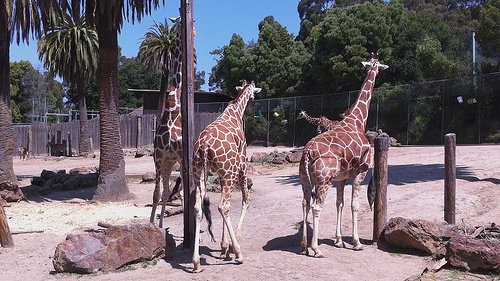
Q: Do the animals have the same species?
A: Yes, all the animals are giraffes.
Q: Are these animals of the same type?
A: Yes, all the animals are giraffes.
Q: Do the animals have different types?
A: No, all the animals are giraffes.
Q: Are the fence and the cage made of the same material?
A: Yes, both the fence and the cage are made of metal.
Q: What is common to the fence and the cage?
A: The material, both the fence and the cage are metallic.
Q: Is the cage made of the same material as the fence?
A: Yes, both the cage and the fence are made of metal.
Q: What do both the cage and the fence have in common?
A: The material, both the cage and the fence are metallic.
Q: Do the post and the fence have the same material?
A: No, the post is made of wood and the fence is made of metal.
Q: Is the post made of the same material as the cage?
A: No, the post is made of wood and the cage is made of metal.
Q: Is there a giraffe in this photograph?
A: Yes, there is a giraffe.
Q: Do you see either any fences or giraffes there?
A: Yes, there is a giraffe.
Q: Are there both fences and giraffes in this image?
A: Yes, there are both a giraffe and a fence.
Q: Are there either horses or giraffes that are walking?
A: Yes, the giraffe is walking.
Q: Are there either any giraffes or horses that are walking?
A: Yes, the giraffe is walking.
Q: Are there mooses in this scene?
A: No, there are no mooses.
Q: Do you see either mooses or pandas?
A: No, there are no mooses or pandas.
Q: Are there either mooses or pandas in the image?
A: No, there are no mooses or pandas.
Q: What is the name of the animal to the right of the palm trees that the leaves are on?
A: The animal is a giraffe.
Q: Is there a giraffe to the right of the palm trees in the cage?
A: Yes, there is a giraffe to the right of the palm trees.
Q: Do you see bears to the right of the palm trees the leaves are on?
A: No, there is a giraffe to the right of the palm trees.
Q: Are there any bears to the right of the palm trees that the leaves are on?
A: No, there is a giraffe to the right of the palm trees.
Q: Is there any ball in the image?
A: No, there are no balls.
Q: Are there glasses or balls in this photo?
A: No, there are no balls or glasses.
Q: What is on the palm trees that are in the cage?
A: The leaves are on the palm trees.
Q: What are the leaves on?
A: The leaves are on the palm trees.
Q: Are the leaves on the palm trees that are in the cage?
A: Yes, the leaves are on the palm trees.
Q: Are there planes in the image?
A: No, there are no planes.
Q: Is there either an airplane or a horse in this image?
A: No, there are no airplanes or horses.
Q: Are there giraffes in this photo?
A: Yes, there is a giraffe.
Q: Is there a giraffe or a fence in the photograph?
A: Yes, there is a giraffe.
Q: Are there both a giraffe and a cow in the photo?
A: No, there is a giraffe but no cows.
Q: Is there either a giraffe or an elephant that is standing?
A: Yes, the giraffe is standing.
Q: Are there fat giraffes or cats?
A: Yes, there is a fat giraffe.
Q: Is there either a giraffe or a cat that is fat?
A: Yes, the giraffe is fat.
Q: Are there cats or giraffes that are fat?
A: Yes, the giraffe is fat.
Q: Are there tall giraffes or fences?
A: Yes, there is a tall giraffe.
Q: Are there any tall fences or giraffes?
A: Yes, there is a tall giraffe.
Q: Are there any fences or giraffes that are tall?
A: Yes, the giraffe is tall.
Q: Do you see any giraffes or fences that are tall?
A: Yes, the giraffe is tall.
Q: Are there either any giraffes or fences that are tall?
A: Yes, the giraffe is tall.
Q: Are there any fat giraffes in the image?
A: Yes, there is a fat giraffe.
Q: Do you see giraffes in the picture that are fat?
A: Yes, there is a giraffe that is fat.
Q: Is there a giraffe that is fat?
A: Yes, there is a giraffe that is fat.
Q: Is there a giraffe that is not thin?
A: Yes, there is a fat giraffe.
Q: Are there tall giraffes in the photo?
A: Yes, there is a tall giraffe.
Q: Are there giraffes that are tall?
A: Yes, there is a giraffe that is tall.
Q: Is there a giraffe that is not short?
A: Yes, there is a tall giraffe.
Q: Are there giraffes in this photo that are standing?
A: Yes, there is a giraffe that is standing.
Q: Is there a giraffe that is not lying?
A: Yes, there is a giraffe that is standing.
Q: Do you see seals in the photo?
A: No, there are no seals.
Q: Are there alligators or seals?
A: No, there are no seals or alligators.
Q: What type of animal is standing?
A: The animal is a giraffe.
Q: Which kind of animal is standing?
A: The animal is a giraffe.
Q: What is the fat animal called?
A: The animal is a giraffe.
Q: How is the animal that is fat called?
A: The animal is a giraffe.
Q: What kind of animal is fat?
A: The animal is a giraffe.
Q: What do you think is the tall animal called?
A: The animal is a giraffe.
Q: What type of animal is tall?
A: The animal is a giraffe.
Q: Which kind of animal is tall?
A: The animal is a giraffe.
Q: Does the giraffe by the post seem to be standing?
A: Yes, the giraffe is standing.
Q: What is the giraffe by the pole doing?
A: The giraffe is standing.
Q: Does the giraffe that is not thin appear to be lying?
A: No, the giraffe is standing.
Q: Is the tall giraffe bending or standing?
A: The giraffe is standing.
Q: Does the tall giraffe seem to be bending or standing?
A: The giraffe is standing.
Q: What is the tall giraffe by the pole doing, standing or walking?
A: The giraffe is standing.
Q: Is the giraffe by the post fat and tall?
A: Yes, the giraffe is fat and tall.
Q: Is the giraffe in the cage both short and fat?
A: No, the giraffe is fat but tall.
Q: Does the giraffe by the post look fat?
A: Yes, the giraffe is fat.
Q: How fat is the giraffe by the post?
A: The giraffe is fat.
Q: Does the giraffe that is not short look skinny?
A: No, the giraffe is fat.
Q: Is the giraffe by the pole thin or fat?
A: The giraffe is fat.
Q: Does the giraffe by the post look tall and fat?
A: Yes, the giraffe is tall and fat.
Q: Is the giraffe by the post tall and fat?
A: Yes, the giraffe is tall and fat.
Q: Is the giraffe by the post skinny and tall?
A: No, the giraffe is tall but fat.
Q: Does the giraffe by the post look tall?
A: Yes, the giraffe is tall.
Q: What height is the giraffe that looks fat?
A: The giraffe is tall.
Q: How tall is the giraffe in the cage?
A: The giraffe is tall.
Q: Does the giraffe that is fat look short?
A: No, the giraffe is tall.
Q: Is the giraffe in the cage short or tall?
A: The giraffe is tall.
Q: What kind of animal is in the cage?
A: The animal is a giraffe.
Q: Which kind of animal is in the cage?
A: The animal is a giraffe.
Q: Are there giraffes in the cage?
A: Yes, there is a giraffe in the cage.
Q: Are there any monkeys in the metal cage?
A: No, there is a giraffe in the cage.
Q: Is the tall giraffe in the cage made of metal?
A: Yes, the giraffe is in the cage.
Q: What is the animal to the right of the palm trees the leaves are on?
A: The animal is a giraffe.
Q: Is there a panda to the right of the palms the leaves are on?
A: No, there is a giraffe to the right of the palms.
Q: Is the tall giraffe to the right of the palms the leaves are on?
A: Yes, the giraffe is to the right of the palm trees.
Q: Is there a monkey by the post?
A: No, there is a giraffe by the post.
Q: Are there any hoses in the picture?
A: No, there are no hoses.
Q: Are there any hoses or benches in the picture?
A: No, there are no hoses or benches.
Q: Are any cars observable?
A: No, there are no cars.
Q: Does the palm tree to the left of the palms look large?
A: Yes, the palm tree is large.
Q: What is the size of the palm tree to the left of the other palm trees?
A: The palm is large.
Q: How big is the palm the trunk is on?
A: The palm tree is large.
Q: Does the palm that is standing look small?
A: No, the palm tree is large.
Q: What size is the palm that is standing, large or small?
A: The palm tree is large.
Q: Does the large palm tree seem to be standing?
A: Yes, the palm is standing.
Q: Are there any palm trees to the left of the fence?
A: Yes, there is a palm tree to the left of the fence.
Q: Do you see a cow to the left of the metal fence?
A: No, there is a palm tree to the left of the fence.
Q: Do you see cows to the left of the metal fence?
A: No, there is a palm tree to the left of the fence.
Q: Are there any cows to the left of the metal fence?
A: No, there is a palm tree to the left of the fence.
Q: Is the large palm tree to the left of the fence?
A: Yes, the palm tree is to the left of the fence.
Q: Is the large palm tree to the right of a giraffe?
A: No, the palm tree is to the left of a giraffe.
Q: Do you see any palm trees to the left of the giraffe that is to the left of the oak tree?
A: Yes, there is a palm tree to the left of the giraffe.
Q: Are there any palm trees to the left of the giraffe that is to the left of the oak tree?
A: Yes, there is a palm tree to the left of the giraffe.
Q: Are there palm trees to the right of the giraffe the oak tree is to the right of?
A: No, the palm tree is to the left of the giraffe.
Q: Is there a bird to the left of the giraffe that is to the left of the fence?
A: No, there is a palm tree to the left of the giraffe.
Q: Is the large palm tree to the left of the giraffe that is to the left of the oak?
A: Yes, the palm tree is to the left of the giraffe.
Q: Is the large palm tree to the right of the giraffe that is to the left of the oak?
A: No, the palm tree is to the left of the giraffe.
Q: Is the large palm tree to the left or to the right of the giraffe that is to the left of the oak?
A: The palm tree is to the left of the giraffe.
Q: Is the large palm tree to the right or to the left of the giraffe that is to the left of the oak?
A: The palm tree is to the left of the giraffe.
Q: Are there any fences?
A: Yes, there is a fence.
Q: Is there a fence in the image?
A: Yes, there is a fence.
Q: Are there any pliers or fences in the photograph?
A: Yes, there is a fence.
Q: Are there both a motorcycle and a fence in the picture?
A: No, there is a fence but no motorcycles.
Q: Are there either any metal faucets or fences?
A: Yes, there is a metal fence.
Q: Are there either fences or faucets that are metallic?
A: Yes, the fence is metallic.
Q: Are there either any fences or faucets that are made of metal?
A: Yes, the fence is made of metal.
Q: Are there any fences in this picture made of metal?
A: Yes, there is a fence that is made of metal.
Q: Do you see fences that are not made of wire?
A: Yes, there is a fence that is made of metal.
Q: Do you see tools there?
A: No, there are no tools.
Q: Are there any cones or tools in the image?
A: No, there are no tools or cones.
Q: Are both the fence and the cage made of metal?
A: Yes, both the fence and the cage are made of metal.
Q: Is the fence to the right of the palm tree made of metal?
A: Yes, the fence is made of metal.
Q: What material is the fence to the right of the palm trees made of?
A: The fence is made of metal.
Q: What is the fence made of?
A: The fence is made of metal.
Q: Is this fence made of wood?
A: No, the fence is made of metal.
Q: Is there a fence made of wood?
A: No, there is a fence but it is made of metal.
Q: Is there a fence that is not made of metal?
A: No, there is a fence but it is made of metal.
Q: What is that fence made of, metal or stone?
A: The fence is made of metal.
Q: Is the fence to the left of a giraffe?
A: No, the fence is to the right of a giraffe.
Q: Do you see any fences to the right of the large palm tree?
A: Yes, there is a fence to the right of the palm tree.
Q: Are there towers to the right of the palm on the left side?
A: No, there is a fence to the right of the palm.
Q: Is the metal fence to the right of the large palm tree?
A: Yes, the fence is to the right of the palm.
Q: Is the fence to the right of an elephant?
A: No, the fence is to the right of the palm.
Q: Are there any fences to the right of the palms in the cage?
A: Yes, there is a fence to the right of the palm trees.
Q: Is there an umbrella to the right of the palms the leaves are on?
A: No, there is a fence to the right of the palms.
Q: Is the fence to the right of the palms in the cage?
A: Yes, the fence is to the right of the palm trees.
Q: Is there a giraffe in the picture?
A: Yes, there is a giraffe.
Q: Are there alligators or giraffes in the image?
A: Yes, there is a giraffe.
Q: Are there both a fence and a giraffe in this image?
A: Yes, there are both a giraffe and a fence.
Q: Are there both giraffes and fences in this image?
A: Yes, there are both a giraffe and a fence.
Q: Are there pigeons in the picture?
A: No, there are no pigeons.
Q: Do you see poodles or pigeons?
A: No, there are no pigeons or poodles.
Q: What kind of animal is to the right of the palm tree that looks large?
A: The animal is a giraffe.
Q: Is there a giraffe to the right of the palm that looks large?
A: Yes, there is a giraffe to the right of the palm tree.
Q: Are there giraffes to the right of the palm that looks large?
A: Yes, there is a giraffe to the right of the palm tree.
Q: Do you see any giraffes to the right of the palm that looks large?
A: Yes, there is a giraffe to the right of the palm tree.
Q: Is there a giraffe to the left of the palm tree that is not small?
A: No, the giraffe is to the right of the palm tree.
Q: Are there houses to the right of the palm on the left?
A: No, there is a giraffe to the right of the palm.